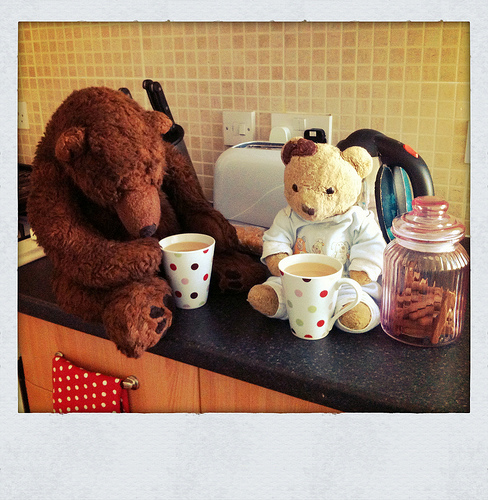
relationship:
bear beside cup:
[19, 85, 269, 360] [152, 225, 219, 315]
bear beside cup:
[241, 125, 390, 346] [270, 251, 368, 348]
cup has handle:
[270, 251, 368, 348] [328, 277, 364, 332]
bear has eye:
[241, 125, 390, 346] [285, 179, 307, 195]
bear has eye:
[241, 125, 390, 346] [321, 182, 344, 198]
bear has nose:
[19, 85, 269, 360] [116, 192, 164, 245]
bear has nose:
[241, 125, 390, 346] [289, 197, 323, 218]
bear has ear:
[19, 85, 269, 360] [49, 123, 94, 166]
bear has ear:
[19, 85, 269, 360] [142, 108, 176, 142]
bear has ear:
[241, 125, 390, 346] [338, 145, 380, 177]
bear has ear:
[241, 125, 390, 346] [271, 131, 309, 159]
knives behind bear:
[112, 70, 207, 205] [19, 85, 269, 360]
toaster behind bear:
[199, 132, 319, 236] [241, 125, 390, 346]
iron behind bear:
[332, 130, 446, 274] [241, 125, 390, 346]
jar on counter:
[376, 191, 476, 356] [19, 213, 472, 416]